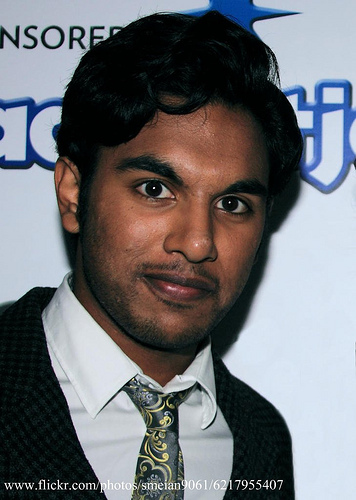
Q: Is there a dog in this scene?
A: No, there are no dogs.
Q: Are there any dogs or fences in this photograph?
A: No, there are no dogs or fences.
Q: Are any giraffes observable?
A: No, there are no giraffes.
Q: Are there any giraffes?
A: No, there are no giraffes.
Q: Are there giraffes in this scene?
A: No, there are no giraffes.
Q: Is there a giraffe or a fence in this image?
A: No, there are no giraffes or fences.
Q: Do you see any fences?
A: No, there are no fences.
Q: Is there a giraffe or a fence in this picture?
A: No, there are no fences or giraffes.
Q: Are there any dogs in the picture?
A: No, there are no dogs.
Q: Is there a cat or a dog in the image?
A: No, there are no dogs or cats.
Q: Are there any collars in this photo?
A: Yes, there is a collar.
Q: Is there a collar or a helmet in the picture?
A: Yes, there is a collar.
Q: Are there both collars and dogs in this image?
A: No, there is a collar but no dogs.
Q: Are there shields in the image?
A: No, there are no shields.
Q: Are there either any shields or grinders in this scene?
A: No, there are no shields or grinders.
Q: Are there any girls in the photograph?
A: No, there are no girls.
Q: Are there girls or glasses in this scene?
A: No, there are no girls or glasses.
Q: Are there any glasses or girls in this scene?
A: No, there are no girls or glasses.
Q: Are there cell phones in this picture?
A: No, there are no cell phones.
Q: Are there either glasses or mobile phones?
A: No, there are no mobile phones or glasses.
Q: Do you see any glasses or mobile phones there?
A: No, there are no mobile phones or glasses.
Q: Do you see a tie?
A: Yes, there is a tie.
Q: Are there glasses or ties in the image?
A: Yes, there is a tie.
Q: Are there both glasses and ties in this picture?
A: No, there is a tie but no glasses.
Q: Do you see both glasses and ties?
A: No, there is a tie but no glasses.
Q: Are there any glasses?
A: No, there are no glasses.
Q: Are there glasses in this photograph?
A: No, there are no glasses.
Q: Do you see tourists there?
A: No, there are no tourists.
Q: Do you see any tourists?
A: No, there are no tourists.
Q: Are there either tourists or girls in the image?
A: No, there are no tourists or girls.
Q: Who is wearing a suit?
A: The man is wearing a suit.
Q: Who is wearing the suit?
A: The man is wearing a suit.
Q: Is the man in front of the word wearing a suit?
A: Yes, the man is wearing a suit.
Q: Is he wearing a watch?
A: No, the man is wearing a suit.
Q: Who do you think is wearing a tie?
A: The man is wearing a tie.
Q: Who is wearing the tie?
A: The man is wearing a tie.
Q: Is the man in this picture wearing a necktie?
A: Yes, the man is wearing a necktie.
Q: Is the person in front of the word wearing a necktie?
A: Yes, the man is wearing a necktie.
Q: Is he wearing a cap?
A: No, the man is wearing a necktie.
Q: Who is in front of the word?
A: The man is in front of the word.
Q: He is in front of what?
A: The man is in front of the word.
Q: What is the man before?
A: The man is in front of the word.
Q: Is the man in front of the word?
A: Yes, the man is in front of the word.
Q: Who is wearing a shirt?
A: The man is wearing a shirt.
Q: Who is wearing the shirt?
A: The man is wearing a shirt.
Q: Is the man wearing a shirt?
A: Yes, the man is wearing a shirt.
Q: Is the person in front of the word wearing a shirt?
A: Yes, the man is wearing a shirt.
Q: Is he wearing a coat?
A: No, the man is wearing a shirt.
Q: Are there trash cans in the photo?
A: No, there are no trash cans.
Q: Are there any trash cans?
A: No, there are no trash cans.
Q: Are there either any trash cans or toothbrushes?
A: No, there are no trash cans or toothbrushes.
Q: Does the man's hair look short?
A: Yes, the hair is short.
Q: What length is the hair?
A: The hair is short.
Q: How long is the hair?
A: The hair is short.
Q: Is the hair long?
A: No, the hair is short.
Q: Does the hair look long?
A: No, the hair is short.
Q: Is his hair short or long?
A: The hair is short.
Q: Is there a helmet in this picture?
A: No, there are no helmets.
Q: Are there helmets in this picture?
A: No, there are no helmets.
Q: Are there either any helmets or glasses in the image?
A: No, there are no helmets or glasses.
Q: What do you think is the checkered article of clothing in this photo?
A: The clothing item is a suit.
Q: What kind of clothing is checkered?
A: The clothing is a suit.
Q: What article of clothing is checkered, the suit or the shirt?
A: The suit is checkered.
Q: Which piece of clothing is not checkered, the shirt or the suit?
A: The shirt is not checkered.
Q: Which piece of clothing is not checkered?
A: The clothing item is a shirt.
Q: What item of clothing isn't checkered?
A: The clothing item is a shirt.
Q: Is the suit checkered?
A: Yes, the suit is checkered.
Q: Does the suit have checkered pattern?
A: Yes, the suit is checkered.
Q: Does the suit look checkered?
A: Yes, the suit is checkered.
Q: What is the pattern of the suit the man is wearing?
A: The suit is checkered.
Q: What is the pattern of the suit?
A: The suit is checkered.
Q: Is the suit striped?
A: No, the suit is checkered.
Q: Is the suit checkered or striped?
A: The suit is checkered.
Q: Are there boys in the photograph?
A: No, there are no boys.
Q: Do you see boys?
A: No, there are no boys.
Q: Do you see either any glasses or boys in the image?
A: No, there are no boys or glasses.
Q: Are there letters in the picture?
A: Yes, there are letters.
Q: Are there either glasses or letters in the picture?
A: Yes, there are letters.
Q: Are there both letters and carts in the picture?
A: No, there are letters but no carts.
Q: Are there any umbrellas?
A: No, there are no umbrellas.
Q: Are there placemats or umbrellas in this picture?
A: No, there are no umbrellas or placemats.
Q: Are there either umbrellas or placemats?
A: No, there are no umbrellas or placemats.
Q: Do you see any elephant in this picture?
A: No, there are no elephants.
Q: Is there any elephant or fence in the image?
A: No, there are no elephants or fences.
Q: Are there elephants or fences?
A: No, there are no elephants or fences.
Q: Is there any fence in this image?
A: No, there are no fences.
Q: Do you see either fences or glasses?
A: No, there are no fences or glasses.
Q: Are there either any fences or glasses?
A: No, there are no fences or glasses.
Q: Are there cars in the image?
A: No, there are no cars.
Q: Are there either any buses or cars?
A: No, there are no cars or buses.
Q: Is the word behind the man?
A: Yes, the word is behind the man.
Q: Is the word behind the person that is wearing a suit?
A: Yes, the word is behind the man.